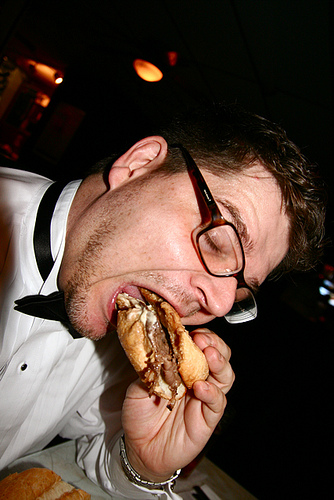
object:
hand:
[119, 325, 236, 481]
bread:
[0, 465, 75, 500]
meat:
[137, 303, 182, 389]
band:
[114, 432, 182, 491]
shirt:
[0, 164, 188, 500]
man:
[0, 109, 331, 500]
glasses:
[177, 146, 257, 326]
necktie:
[12, 177, 68, 328]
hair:
[177, 109, 326, 272]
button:
[19, 361, 28, 372]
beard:
[65, 178, 144, 343]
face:
[63, 134, 291, 342]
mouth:
[103, 275, 184, 330]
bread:
[113, 286, 210, 414]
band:
[31, 173, 85, 285]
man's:
[76, 121, 277, 354]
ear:
[107, 134, 167, 190]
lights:
[130, 53, 164, 84]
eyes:
[201, 223, 223, 256]